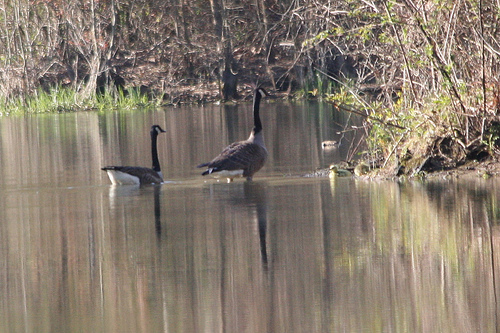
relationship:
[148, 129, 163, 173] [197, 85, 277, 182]
neck on a animal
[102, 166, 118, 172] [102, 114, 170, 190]
feather covering bird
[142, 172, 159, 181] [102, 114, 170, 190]
feather covering bird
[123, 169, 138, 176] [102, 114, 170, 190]
feather covering bird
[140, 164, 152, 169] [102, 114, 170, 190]
feather covering bird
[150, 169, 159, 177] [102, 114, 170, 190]
feather covering bird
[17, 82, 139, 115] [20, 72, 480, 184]
grass growing on shore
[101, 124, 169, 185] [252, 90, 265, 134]
animal having long neck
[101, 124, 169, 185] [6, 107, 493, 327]
animal resting on water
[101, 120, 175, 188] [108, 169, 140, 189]
animal with accents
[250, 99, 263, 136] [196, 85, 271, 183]
neck on bird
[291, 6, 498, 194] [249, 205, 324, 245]
plant next to water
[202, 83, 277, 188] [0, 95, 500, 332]
animal standing in still water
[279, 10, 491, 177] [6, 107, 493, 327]
brush reflected of water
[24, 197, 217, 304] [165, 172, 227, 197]
still water has little ripples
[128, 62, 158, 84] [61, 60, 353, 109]
fallen leaves on bank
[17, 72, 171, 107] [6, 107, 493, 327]
grass patch in water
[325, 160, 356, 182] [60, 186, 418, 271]
duck in water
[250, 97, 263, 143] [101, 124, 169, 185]
neck of animal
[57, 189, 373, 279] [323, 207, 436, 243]
reflections on water